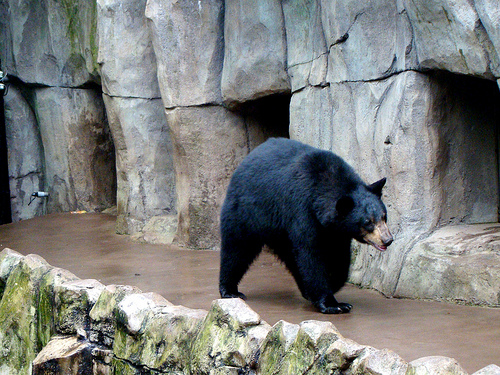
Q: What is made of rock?
A: The wall.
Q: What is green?
A: The moss.